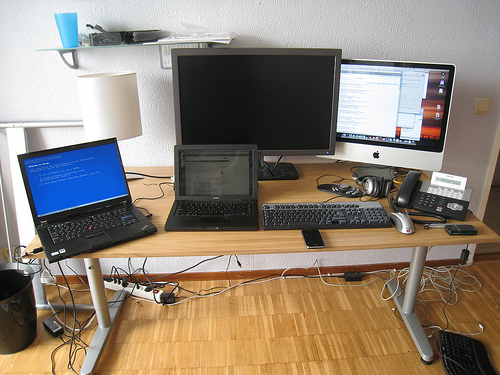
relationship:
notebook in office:
[162, 144, 259, 233] [2, 0, 498, 373]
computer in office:
[326, 54, 456, 172] [2, 0, 498, 373]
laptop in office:
[11, 138, 159, 265] [2, 0, 498, 373]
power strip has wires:
[102, 275, 165, 304] [29, 260, 486, 314]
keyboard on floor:
[434, 327, 497, 374] [3, 257, 498, 375]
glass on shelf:
[52, 11, 81, 47] [29, 35, 234, 71]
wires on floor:
[29, 260, 486, 314] [3, 257, 498, 375]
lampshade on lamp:
[76, 72, 144, 143] [76, 74, 147, 183]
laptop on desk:
[11, 138, 159, 265] [17, 160, 500, 374]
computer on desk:
[326, 54, 456, 172] [17, 160, 500, 374]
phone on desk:
[394, 169, 471, 223] [17, 160, 500, 374]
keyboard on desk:
[260, 201, 394, 231] [17, 160, 500, 374]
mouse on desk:
[388, 209, 416, 235] [17, 160, 500, 374]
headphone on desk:
[357, 174, 395, 200] [17, 160, 500, 374]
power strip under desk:
[102, 275, 165, 304] [17, 160, 500, 374]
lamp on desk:
[76, 74, 147, 183] [17, 160, 500, 374]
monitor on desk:
[168, 47, 342, 182] [17, 160, 500, 374]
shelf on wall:
[29, 35, 234, 71] [1, 4, 499, 170]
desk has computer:
[17, 160, 500, 374] [326, 54, 456, 172]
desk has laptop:
[17, 160, 500, 374] [11, 138, 159, 265]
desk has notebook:
[17, 160, 500, 374] [162, 144, 259, 233]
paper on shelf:
[156, 32, 234, 43] [29, 35, 234, 71]